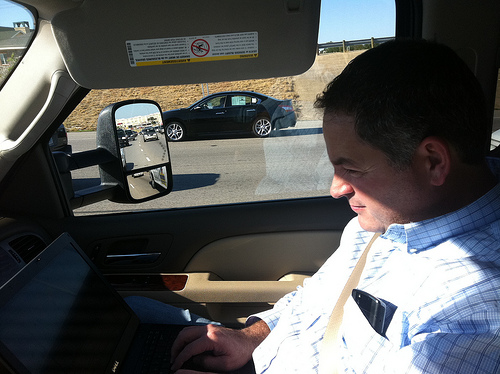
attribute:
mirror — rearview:
[101, 80, 188, 190]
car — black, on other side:
[162, 88, 299, 139]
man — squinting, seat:
[189, 32, 486, 372]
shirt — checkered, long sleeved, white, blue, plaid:
[246, 198, 488, 372]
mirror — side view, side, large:
[98, 99, 172, 204]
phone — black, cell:
[348, 281, 389, 332]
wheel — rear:
[254, 118, 272, 138]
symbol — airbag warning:
[189, 34, 210, 59]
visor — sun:
[56, 15, 321, 93]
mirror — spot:
[123, 161, 170, 201]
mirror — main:
[113, 102, 172, 168]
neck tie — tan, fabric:
[316, 232, 390, 366]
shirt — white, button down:
[246, 213, 483, 364]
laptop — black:
[9, 234, 193, 371]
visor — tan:
[49, 10, 322, 83]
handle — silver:
[106, 248, 173, 266]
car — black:
[155, 90, 290, 140]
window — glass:
[201, 94, 227, 114]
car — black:
[161, 90, 297, 142]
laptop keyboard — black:
[114, 320, 241, 371]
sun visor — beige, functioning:
[49, 0, 319, 90]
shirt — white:
[242, 180, 483, 372]